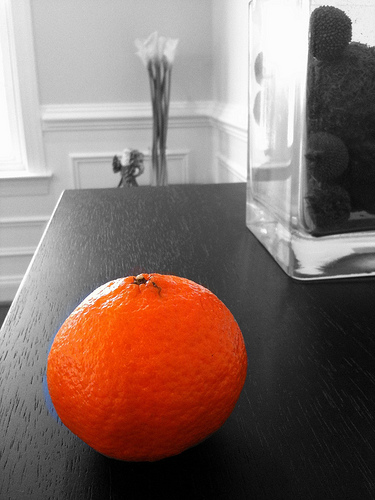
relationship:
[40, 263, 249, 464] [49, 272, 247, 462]
fruit only color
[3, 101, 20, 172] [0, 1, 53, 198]
sulight coming through a window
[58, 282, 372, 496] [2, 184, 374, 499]
shadows on wood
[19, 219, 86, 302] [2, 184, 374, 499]
light reflecting on table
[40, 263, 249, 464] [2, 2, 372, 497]
fruit on counter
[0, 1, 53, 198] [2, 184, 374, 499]
window by a table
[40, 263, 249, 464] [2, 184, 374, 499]
fruit on a table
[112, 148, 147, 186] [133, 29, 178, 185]
statue near flowers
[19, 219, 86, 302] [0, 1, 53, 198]
light coming through windows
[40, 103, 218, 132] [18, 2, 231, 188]
trim on wall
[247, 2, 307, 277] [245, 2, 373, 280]
reflection on a vase